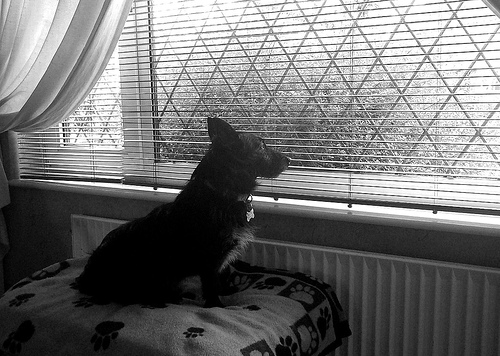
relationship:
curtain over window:
[0, 0, 135, 259] [0, 1, 497, 224]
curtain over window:
[0, 0, 174, 194] [110, 3, 481, 236]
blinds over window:
[14, 0, 497, 215] [149, 0, 498, 215]